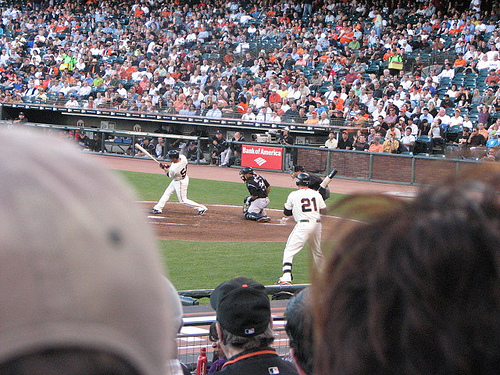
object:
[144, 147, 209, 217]
player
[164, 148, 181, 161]
helmet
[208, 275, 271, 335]
cap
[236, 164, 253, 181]
helmet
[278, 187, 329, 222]
shirt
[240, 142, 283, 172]
sign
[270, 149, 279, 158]
letters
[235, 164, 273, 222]
catcher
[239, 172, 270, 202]
shirt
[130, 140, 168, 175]
bat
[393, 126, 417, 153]
fans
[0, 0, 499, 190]
bleachers